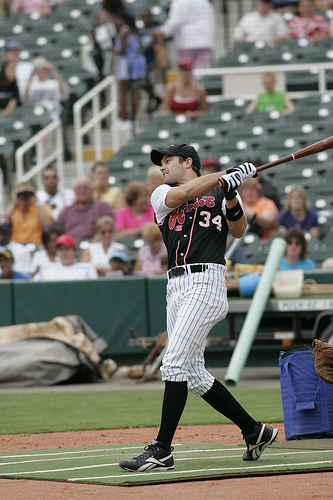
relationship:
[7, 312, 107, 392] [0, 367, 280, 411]
tarp on ground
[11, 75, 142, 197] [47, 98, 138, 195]
railing on steps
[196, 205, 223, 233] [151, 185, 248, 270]
number on jersey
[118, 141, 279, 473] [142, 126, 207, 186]
man wearing hat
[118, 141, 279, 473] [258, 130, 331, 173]
man swinging bat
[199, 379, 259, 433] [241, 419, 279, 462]
stocking in sneaker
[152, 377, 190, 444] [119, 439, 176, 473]
stocking in shoe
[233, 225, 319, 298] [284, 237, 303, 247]
woman in sunglasses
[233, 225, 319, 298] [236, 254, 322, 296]
woman in shirt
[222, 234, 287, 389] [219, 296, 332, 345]
gray pipe leaning against trailer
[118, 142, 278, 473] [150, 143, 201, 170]
man wears cap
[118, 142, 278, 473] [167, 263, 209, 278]
man wears belt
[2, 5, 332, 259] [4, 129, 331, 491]
audience watch game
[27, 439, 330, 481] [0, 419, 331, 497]
mat sitting on dirt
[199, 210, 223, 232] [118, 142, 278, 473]
number on man